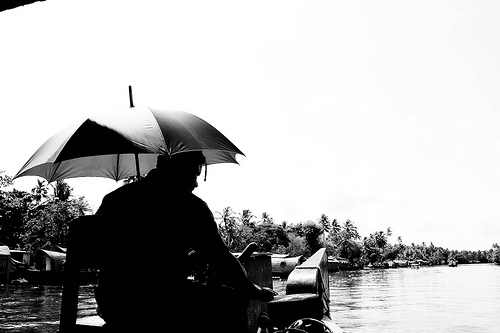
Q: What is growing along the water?
A: Trees.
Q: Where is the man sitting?
A: On a boat.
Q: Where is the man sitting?
A: Under an umbrella.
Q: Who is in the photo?
A: A man.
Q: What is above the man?
A: An umbrella.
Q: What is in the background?
A: Water.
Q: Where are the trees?
A: Near the man.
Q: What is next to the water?
A: Trees.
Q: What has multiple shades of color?
A: An umbrella.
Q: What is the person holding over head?
A: Umbrella.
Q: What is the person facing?
A: Water.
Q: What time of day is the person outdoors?
A: Noon.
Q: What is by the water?
A: Trees.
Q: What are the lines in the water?
A: Ripples.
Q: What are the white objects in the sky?
A: Clouds.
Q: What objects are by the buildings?
A: Trees.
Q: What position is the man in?
A: Sitting.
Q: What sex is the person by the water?
A: Male.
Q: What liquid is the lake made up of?
A: Water.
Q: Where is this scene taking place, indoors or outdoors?
A: In the outdoors.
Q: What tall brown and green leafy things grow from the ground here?
A: Trees.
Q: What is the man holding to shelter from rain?
A: Umbrella.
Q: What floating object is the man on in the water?
A: Boat.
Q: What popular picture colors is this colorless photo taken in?
A: Black and white.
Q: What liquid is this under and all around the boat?
A: Water.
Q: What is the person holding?
A: An umbrella.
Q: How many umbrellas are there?
A: One.